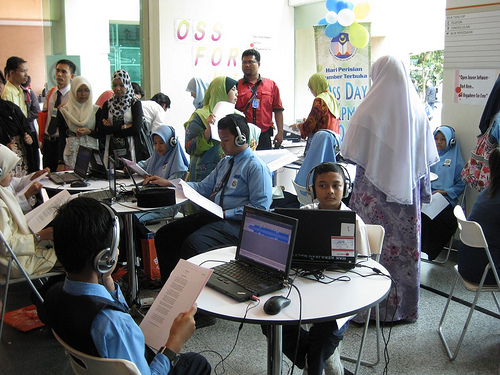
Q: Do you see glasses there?
A: No, there are no glasses.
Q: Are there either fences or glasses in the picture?
A: No, there are no glasses or fences.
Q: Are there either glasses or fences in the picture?
A: No, there are no glasses or fences.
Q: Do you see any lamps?
A: No, there are no lamps.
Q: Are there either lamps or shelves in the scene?
A: No, there are no lamps or shelves.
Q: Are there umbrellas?
A: No, there are no umbrellas.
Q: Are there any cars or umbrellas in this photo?
A: No, there are no umbrellas or cars.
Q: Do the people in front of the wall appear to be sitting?
A: Yes, the people are sitting.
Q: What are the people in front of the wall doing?
A: The people are sitting.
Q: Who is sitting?
A: The people are sitting.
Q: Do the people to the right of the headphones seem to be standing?
A: No, the people are sitting.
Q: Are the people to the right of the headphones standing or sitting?
A: The people are sitting.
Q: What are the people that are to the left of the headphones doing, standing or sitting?
A: The people are sitting.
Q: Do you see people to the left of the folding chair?
A: Yes, there are people to the left of the folding chair.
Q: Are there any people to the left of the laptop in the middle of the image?
A: Yes, there are people to the left of the laptop computer.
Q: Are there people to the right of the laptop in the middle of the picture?
A: No, the people are to the left of the laptop computer.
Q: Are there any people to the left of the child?
A: Yes, there are people to the left of the child.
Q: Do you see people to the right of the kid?
A: No, the people are to the left of the kid.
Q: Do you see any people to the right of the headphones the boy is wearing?
A: Yes, there are people to the right of the headphones.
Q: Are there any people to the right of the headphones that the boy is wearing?
A: Yes, there are people to the right of the headphones.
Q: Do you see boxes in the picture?
A: No, there are no boxes.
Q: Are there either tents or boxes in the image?
A: No, there are no boxes or tents.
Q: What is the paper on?
A: The paper is on the wall.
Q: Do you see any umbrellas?
A: No, there are no umbrellas.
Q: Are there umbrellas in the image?
A: No, there are no umbrellas.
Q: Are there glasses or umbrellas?
A: No, there are no umbrellas or glasses.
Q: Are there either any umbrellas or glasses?
A: No, there are no umbrellas or glasses.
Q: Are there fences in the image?
A: No, there are no fences.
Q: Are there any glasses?
A: No, there are no glasses.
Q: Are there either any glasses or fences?
A: No, there are no glasses or fences.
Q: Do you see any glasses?
A: No, there are no glasses.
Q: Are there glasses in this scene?
A: No, there are no glasses.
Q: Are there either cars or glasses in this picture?
A: No, there are no glasses or cars.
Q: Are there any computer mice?
A: Yes, there is a computer mouse.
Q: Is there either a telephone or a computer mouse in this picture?
A: Yes, there is a computer mouse.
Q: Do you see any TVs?
A: No, there are no tvs.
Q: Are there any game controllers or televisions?
A: No, there are no televisions or game controllers.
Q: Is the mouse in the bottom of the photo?
A: Yes, the mouse is in the bottom of the image.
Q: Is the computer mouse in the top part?
A: No, the computer mouse is in the bottom of the image.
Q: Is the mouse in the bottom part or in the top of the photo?
A: The mouse is in the bottom of the image.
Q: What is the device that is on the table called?
A: The device is a computer mouse.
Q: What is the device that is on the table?
A: The device is a computer mouse.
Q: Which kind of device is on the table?
A: The device is a computer mouse.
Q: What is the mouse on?
A: The mouse is on the table.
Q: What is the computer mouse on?
A: The mouse is on the table.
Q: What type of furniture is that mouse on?
A: The mouse is on the table.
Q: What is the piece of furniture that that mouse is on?
A: The piece of furniture is a table.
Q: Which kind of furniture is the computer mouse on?
A: The mouse is on the table.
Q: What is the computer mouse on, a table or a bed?
A: The computer mouse is on a table.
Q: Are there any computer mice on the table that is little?
A: Yes, there is a computer mouse on the table.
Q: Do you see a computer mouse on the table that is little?
A: Yes, there is a computer mouse on the table.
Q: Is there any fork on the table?
A: No, there is a computer mouse on the table.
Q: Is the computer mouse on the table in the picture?
A: Yes, the computer mouse is on the table.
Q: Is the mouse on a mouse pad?
A: No, the mouse is on the table.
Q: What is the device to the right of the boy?
A: The device is a computer mouse.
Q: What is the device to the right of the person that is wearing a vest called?
A: The device is a computer mouse.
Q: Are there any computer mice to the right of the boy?
A: Yes, there is a computer mouse to the right of the boy.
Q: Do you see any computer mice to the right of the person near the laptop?
A: Yes, there is a computer mouse to the right of the boy.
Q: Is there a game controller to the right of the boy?
A: No, there is a computer mouse to the right of the boy.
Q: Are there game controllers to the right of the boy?
A: No, there is a computer mouse to the right of the boy.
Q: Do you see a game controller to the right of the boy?
A: No, there is a computer mouse to the right of the boy.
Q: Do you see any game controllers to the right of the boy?
A: No, there is a computer mouse to the right of the boy.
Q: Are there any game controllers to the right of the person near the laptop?
A: No, there is a computer mouse to the right of the boy.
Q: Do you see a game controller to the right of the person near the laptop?
A: No, there is a computer mouse to the right of the boy.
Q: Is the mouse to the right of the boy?
A: Yes, the mouse is to the right of the boy.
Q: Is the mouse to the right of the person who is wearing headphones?
A: Yes, the mouse is to the right of the boy.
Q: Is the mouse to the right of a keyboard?
A: No, the mouse is to the right of the boy.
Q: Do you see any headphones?
A: Yes, there are headphones.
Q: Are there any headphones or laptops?
A: Yes, there are headphones.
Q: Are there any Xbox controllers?
A: No, there are no Xbox controllers.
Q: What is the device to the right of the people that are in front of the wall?
A: The device is headphones.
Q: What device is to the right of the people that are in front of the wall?
A: The device is headphones.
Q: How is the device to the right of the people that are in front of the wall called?
A: The device is headphones.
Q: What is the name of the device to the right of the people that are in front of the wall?
A: The device is headphones.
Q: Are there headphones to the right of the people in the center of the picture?
A: Yes, there are headphones to the right of the people.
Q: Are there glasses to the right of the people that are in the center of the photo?
A: No, there are headphones to the right of the people.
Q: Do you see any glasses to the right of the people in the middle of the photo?
A: No, there are headphones to the right of the people.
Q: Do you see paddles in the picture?
A: No, there are no paddles.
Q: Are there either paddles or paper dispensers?
A: No, there are no paddles or paper dispensers.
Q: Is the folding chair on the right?
A: Yes, the folding chair is on the right of the image.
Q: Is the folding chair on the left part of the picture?
A: No, the folding chair is on the right of the image.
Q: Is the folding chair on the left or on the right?
A: The folding chair is on the right of the image.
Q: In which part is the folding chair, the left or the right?
A: The folding chair is on the right of the image.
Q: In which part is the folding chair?
A: The folding chair is on the right of the image.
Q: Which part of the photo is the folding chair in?
A: The folding chair is on the right of the image.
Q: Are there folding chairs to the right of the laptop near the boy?
A: Yes, there is a folding chair to the right of the laptop.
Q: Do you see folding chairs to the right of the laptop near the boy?
A: Yes, there is a folding chair to the right of the laptop.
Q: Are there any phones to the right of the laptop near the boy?
A: No, there is a folding chair to the right of the laptop.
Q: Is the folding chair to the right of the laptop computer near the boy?
A: Yes, the folding chair is to the right of the laptop computer.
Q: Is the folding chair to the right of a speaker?
A: No, the folding chair is to the right of the laptop computer.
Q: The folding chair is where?
A: The folding chair is on the floor.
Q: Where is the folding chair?
A: The folding chair is on the floor.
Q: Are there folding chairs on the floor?
A: Yes, there is a folding chair on the floor.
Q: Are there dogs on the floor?
A: No, there is a folding chair on the floor.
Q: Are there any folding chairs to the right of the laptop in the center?
A: Yes, there is a folding chair to the right of the laptop.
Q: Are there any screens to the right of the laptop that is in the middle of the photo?
A: No, there is a folding chair to the right of the laptop computer.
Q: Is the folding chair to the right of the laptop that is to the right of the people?
A: Yes, the folding chair is to the right of the laptop.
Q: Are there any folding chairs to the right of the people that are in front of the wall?
A: Yes, there is a folding chair to the right of the people.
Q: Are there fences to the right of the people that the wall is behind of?
A: No, there is a folding chair to the right of the people.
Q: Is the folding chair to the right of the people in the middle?
A: Yes, the folding chair is to the right of the people.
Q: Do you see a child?
A: Yes, there is a child.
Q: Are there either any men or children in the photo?
A: Yes, there is a child.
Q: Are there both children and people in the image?
A: Yes, there are both a child and a person.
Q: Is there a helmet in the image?
A: No, there are no helmets.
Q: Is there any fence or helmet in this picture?
A: No, there are no helmets or fences.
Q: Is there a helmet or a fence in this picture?
A: No, there are no helmets or fences.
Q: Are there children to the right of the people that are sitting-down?
A: Yes, there is a child to the right of the people.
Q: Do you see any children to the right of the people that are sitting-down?
A: Yes, there is a child to the right of the people.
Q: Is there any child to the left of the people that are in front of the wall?
A: No, the child is to the right of the people.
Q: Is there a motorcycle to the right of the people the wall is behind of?
A: No, there is a child to the right of the people.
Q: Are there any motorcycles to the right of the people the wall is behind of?
A: No, there is a child to the right of the people.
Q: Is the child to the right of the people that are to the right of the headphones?
A: Yes, the child is to the right of the people.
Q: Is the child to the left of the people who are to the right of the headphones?
A: No, the child is to the right of the people.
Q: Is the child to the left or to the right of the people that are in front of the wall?
A: The child is to the right of the people.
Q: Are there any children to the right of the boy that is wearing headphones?
A: Yes, there is a child to the right of the boy.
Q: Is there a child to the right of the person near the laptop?
A: Yes, there is a child to the right of the boy.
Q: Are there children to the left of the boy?
A: No, the child is to the right of the boy.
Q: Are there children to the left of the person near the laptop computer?
A: No, the child is to the right of the boy.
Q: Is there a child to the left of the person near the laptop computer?
A: No, the child is to the right of the boy.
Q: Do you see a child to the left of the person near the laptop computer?
A: No, the child is to the right of the boy.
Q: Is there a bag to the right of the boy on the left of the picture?
A: No, there is a child to the right of the boy.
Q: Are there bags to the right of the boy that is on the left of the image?
A: No, there is a child to the right of the boy.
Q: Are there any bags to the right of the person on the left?
A: No, there is a child to the right of the boy.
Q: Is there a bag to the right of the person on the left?
A: No, there is a child to the right of the boy.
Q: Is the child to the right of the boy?
A: Yes, the child is to the right of the boy.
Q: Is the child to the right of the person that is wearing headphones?
A: Yes, the child is to the right of the boy.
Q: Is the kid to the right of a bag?
A: No, the kid is to the right of the boy.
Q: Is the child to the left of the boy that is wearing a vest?
A: No, the child is to the right of the boy.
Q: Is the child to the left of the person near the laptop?
A: No, the child is to the right of the boy.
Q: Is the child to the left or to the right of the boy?
A: The child is to the right of the boy.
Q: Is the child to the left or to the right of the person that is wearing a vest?
A: The child is to the right of the boy.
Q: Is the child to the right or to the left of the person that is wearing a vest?
A: The child is to the right of the boy.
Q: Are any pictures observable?
A: No, there are no pictures.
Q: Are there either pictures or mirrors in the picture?
A: No, there are no pictures or mirrors.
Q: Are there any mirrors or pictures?
A: No, there are no pictures or mirrors.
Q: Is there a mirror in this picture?
A: No, there are no mirrors.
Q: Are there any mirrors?
A: No, there are no mirrors.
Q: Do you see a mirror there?
A: No, there are no mirrors.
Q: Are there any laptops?
A: Yes, there is a laptop.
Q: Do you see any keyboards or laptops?
A: Yes, there is a laptop.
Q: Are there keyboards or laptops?
A: Yes, there is a laptop.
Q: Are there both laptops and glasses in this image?
A: No, there is a laptop but no glasses.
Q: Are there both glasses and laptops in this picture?
A: No, there is a laptop but no glasses.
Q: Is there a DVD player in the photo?
A: No, there are no DVD players.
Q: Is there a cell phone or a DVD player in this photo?
A: No, there are no DVD players or cell phones.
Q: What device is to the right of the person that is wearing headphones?
A: The device is a laptop.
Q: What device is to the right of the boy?
A: The device is a laptop.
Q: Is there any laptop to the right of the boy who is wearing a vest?
A: Yes, there is a laptop to the right of the boy.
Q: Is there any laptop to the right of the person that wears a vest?
A: Yes, there is a laptop to the right of the boy.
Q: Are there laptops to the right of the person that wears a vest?
A: Yes, there is a laptop to the right of the boy.